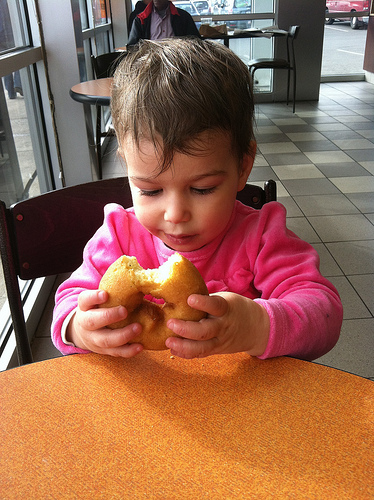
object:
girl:
[50, 38, 341, 363]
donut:
[98, 252, 210, 350]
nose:
[164, 191, 191, 224]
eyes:
[140, 189, 162, 197]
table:
[0, 347, 372, 500]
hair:
[111, 37, 253, 176]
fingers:
[90, 323, 141, 348]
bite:
[124, 253, 183, 284]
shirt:
[50, 201, 342, 362]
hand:
[165, 291, 252, 358]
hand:
[74, 290, 141, 359]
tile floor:
[253, 79, 372, 376]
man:
[124, 0, 200, 41]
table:
[69, 76, 121, 180]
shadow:
[78, 352, 373, 499]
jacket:
[126, 0, 199, 41]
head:
[110, 37, 253, 252]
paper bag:
[199, 24, 227, 38]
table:
[196, 34, 287, 48]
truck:
[325, 0, 371, 29]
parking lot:
[206, 25, 367, 78]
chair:
[247, 25, 300, 112]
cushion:
[247, 58, 288, 68]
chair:
[90, 52, 129, 180]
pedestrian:
[1, 0, 24, 100]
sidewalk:
[0, 81, 42, 314]